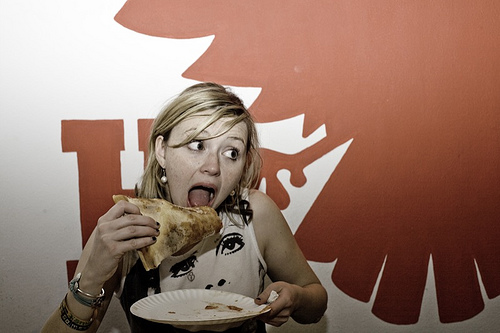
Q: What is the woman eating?
A: Pizza.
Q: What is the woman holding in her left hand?
A: Plate.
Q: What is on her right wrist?
A: Bracelets.